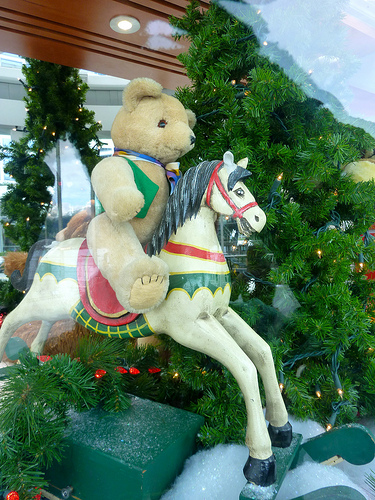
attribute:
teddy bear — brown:
[86, 77, 196, 313]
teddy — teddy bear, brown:
[86, 77, 199, 312]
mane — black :
[162, 158, 213, 242]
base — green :
[238, 422, 374, 499]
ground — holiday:
[312, 87, 358, 121]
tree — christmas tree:
[229, 82, 366, 340]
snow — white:
[162, 406, 362, 498]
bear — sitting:
[79, 72, 202, 319]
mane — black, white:
[148, 151, 226, 245]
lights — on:
[274, 170, 286, 193]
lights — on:
[313, 133, 326, 141]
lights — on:
[226, 77, 238, 89]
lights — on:
[329, 381, 348, 396]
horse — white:
[1, 141, 300, 495]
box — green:
[51, 384, 188, 496]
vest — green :
[81, 145, 182, 242]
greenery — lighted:
[220, 71, 361, 186]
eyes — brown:
[150, 112, 178, 135]